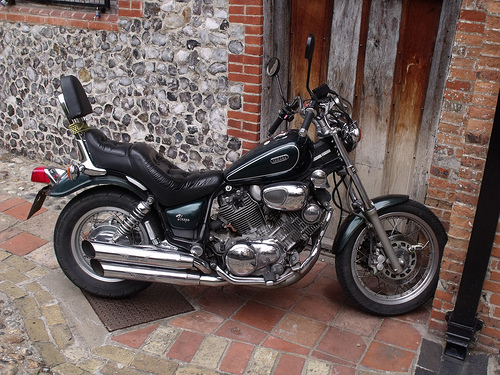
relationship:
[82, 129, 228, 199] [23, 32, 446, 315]
seat on bike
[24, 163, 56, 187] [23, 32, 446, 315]
light on bike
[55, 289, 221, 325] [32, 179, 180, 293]
mat under tire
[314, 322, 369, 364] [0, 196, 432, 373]
brick on ground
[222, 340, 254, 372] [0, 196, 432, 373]
brick on ground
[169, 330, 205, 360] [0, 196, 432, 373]
brick on ground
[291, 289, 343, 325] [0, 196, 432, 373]
brick on ground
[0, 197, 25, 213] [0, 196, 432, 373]
brick on ground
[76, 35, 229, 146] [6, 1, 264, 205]
wall on building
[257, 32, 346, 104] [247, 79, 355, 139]
mirrors on handlebars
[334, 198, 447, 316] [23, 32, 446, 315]
tire on bike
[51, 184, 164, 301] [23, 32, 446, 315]
tire on bike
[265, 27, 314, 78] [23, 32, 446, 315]
mirrors on bike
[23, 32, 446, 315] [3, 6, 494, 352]
bike in front of building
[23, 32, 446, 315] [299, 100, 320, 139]
bike has handlebars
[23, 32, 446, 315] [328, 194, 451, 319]
bike has tire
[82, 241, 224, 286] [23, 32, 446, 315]
exhaust on bike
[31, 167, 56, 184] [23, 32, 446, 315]
red light on bike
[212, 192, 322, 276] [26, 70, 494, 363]
engine on motorcycle